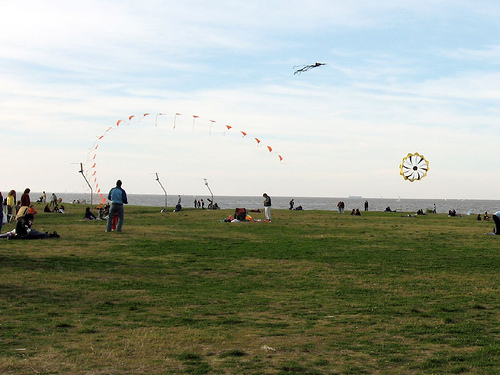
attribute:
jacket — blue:
[105, 183, 129, 208]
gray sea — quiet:
[136, 197, 498, 212]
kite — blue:
[288, 55, 333, 87]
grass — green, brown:
[0, 200, 496, 372]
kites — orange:
[83, 105, 285, 194]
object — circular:
[392, 144, 430, 189]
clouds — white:
[136, 35, 239, 78]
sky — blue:
[111, 25, 193, 97]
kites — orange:
[118, 121, 336, 186]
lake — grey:
[293, 183, 339, 201]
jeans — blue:
[93, 200, 144, 245]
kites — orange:
[92, 110, 284, 208]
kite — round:
[400, 152, 428, 182]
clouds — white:
[277, 82, 499, 147]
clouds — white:
[461, 110, 499, 159]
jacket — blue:
[106, 188, 128, 204]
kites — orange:
[225, 122, 234, 130]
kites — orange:
[278, 154, 283, 161]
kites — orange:
[265, 144, 273, 151]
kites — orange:
[254, 135, 262, 145]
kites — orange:
[239, 130, 248, 136]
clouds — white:
[0, 0, 499, 201]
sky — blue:
[411, 2, 475, 94]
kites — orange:
[74, 107, 309, 199]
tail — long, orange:
[81, 110, 287, 199]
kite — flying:
[289, 53, 331, 80]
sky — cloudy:
[65, 43, 342, 144]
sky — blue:
[1, 2, 483, 199]